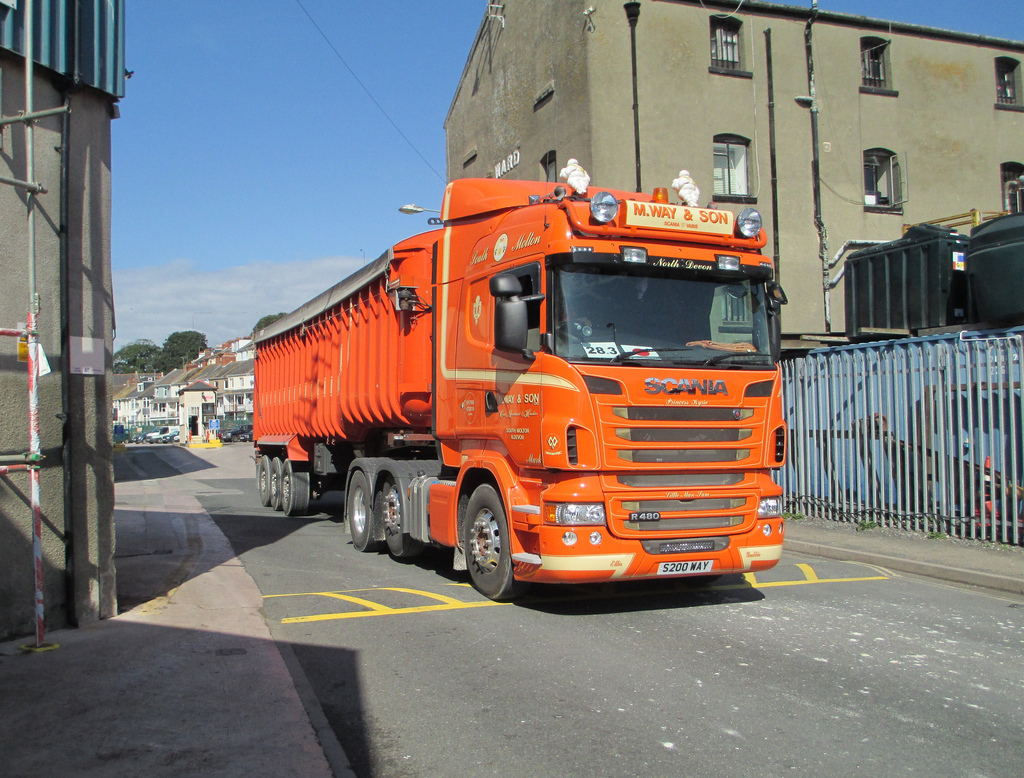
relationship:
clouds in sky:
[100, 248, 377, 370] [175, 68, 226, 116]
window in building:
[859, 113, 910, 190] [656, 107, 873, 185]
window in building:
[859, 22, 898, 86] [690, 57, 1021, 211]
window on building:
[701, 15, 741, 64] [654, 37, 922, 225]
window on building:
[700, 145, 752, 185] [729, 66, 918, 250]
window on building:
[859, 22, 898, 85] [710, 65, 927, 240]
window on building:
[867, 160, 896, 205] [790, 76, 989, 340]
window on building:
[991, 60, 1020, 100] [792, 55, 952, 278]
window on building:
[1004, 163, 1021, 201] [690, 65, 943, 314]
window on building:
[866, 160, 894, 205] [753, 81, 941, 248]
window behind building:
[230, 390, 240, 404] [159, 364, 255, 458]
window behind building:
[144, 397, 170, 417] [120, 371, 187, 434]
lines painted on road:
[261, 526, 894, 650] [329, 547, 511, 681]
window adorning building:
[537, 157, 545, 189] [438, 21, 999, 339]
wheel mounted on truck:
[442, 482, 510, 594] [244, 156, 793, 600]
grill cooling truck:
[603, 397, 755, 540] [244, 156, 793, 600]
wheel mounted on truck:
[251, 444, 273, 505] [244, 156, 793, 600]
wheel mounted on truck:
[264, 446, 286, 507] [244, 156, 793, 600]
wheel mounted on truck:
[277, 459, 314, 512] [244, 156, 793, 600]